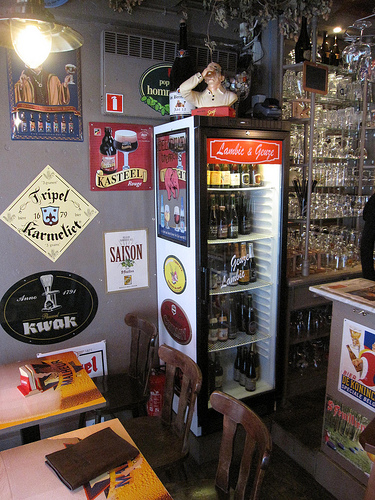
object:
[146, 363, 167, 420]
fire extinguisher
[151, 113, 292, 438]
fridge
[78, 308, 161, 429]
chair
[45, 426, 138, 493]
notebook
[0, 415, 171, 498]
table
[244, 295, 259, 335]
bottle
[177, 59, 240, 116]
sculpture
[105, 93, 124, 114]
sticker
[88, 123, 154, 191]
poster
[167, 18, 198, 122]
bottle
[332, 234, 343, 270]
wine glass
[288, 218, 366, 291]
shelf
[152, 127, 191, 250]
poster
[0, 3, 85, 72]
lamp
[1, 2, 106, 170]
corner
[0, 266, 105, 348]
sign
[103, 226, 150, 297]
sign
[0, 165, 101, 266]
sign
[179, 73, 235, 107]
shirt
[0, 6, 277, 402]
wall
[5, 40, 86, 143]
poster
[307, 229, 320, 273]
wine glasses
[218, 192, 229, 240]
bottles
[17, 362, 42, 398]
package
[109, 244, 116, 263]
word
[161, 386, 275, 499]
chair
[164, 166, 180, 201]
elephant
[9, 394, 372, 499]
floor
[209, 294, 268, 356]
shelf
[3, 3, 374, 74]
ceiling